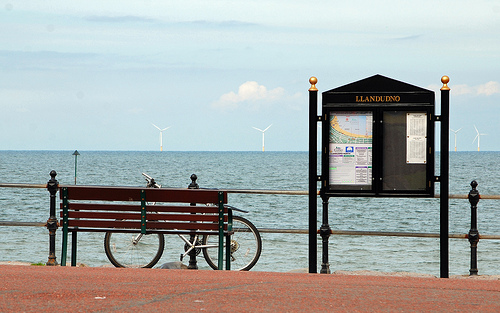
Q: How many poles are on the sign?
A: 2.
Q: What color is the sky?
A: Blue.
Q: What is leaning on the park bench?
A: A bike.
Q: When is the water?
A: Behind the fence.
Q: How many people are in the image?
A: 0.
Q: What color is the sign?
A: Black.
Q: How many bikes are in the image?
A: 1.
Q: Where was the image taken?
A: At the beach.